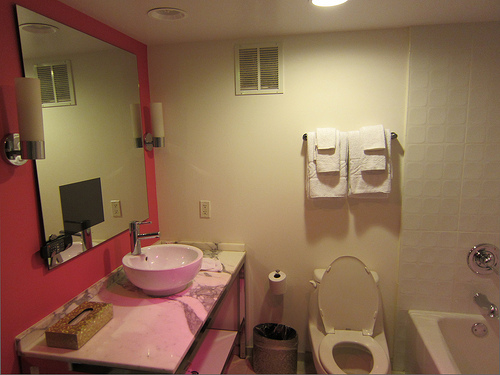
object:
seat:
[311, 325, 396, 375]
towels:
[305, 129, 348, 198]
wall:
[148, 21, 500, 375]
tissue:
[195, 254, 226, 275]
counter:
[21, 242, 245, 369]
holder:
[42, 234, 76, 267]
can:
[251, 319, 300, 372]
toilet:
[308, 252, 400, 375]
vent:
[232, 36, 284, 97]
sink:
[119, 241, 209, 296]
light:
[149, 94, 169, 152]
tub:
[411, 291, 496, 375]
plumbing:
[463, 242, 500, 275]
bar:
[296, 127, 402, 145]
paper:
[268, 268, 286, 298]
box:
[37, 300, 112, 348]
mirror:
[8, 6, 154, 274]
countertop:
[10, 240, 251, 370]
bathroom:
[2, 2, 499, 369]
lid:
[315, 252, 381, 341]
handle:
[309, 280, 319, 291]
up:
[305, 124, 396, 176]